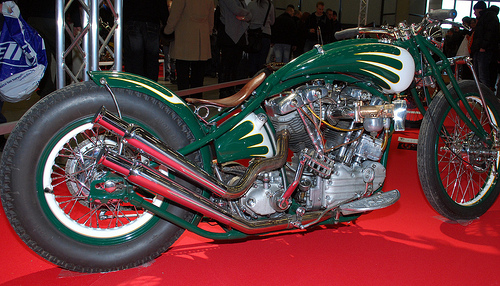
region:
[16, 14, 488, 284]
a really nice bike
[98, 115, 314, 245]
it has dual pipes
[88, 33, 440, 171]
the bike is green & white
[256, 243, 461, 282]
the carpet is red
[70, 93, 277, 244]
the pipes are chrome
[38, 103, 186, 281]
the wheels are trimmed in green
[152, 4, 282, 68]
people are in the background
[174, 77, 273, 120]
the seat is brown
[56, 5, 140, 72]
a steel frame support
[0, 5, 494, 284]
this could be at a bike show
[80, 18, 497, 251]
a motorcycle outside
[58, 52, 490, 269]
a motorcycle that is standing outside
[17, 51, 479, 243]
a green motorcycle that is outside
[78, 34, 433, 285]
a motorcycle that is green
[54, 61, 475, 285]
a motorcycle that is on display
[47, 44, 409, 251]
an old motorcycle on display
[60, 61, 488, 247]
an old motorcycle standing up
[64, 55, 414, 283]
an old green motorcycle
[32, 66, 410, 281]
an old green motorcycle on display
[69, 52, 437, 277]
a motorcycle that is inside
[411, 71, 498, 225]
front wheel of motorcycle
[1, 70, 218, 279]
back wheel of motorcycle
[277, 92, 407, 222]
engine of motorcycle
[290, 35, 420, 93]
tank of motorcycle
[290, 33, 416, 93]
tank of motorcycle is green and white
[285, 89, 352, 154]
red and yellow wires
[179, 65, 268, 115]
passenger site is color brown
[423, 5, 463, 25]
right handle of motorcycle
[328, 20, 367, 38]
left handle of motorcycle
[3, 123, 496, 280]
a red carpet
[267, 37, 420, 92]
green painted bike with white and yellow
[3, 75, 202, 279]
black tire on green and white wheel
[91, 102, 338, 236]
two chrome mufflers on the motorcycle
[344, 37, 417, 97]
white and yellow painted design on green bike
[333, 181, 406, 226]
silver metal foot support on bike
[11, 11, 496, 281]
motorcycle on red platform on display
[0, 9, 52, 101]
blue and white plastic shopping bag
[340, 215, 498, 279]
shadow of motorcycle on red platform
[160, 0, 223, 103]
person behind the bike in beige coat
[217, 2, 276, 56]
people wearing gray and black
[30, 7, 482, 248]
the motorcycle is green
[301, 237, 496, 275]
the floor is red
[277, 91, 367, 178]
the engine of the motorcycle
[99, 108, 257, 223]
the mufflers of the motorcycle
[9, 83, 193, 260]
the rear tire of the motorcycle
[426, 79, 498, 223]
the front tire of the motorcycle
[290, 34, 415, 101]
the fuel tank of the motorcycle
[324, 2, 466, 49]
the handlebars of the motorcycle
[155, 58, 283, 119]
the seat of the motorcycle